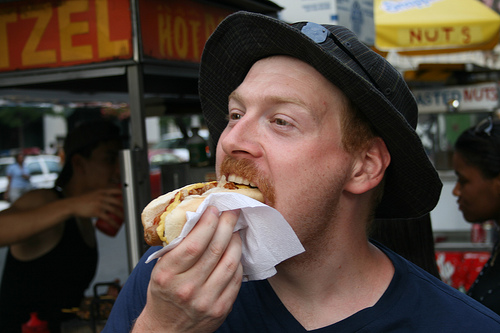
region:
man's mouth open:
[209, 153, 299, 213]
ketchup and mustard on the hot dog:
[146, 184, 283, 226]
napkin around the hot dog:
[168, 193, 328, 284]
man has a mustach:
[216, 158, 288, 195]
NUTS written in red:
[405, 10, 490, 49]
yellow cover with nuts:
[367, 0, 499, 61]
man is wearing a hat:
[187, 19, 477, 239]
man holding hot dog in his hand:
[151, 178, 314, 307]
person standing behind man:
[433, 111, 499, 244]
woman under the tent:
[11, 102, 140, 331]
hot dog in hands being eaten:
[135, 165, 267, 240]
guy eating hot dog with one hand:
[102, 13, 479, 331]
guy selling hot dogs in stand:
[7, 9, 169, 309]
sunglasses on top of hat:
[265, 8, 400, 92]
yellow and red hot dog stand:
[16, 6, 203, 104]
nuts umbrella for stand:
[375, 1, 499, 58]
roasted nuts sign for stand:
[406, 71, 498, 125]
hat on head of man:
[189, 5, 456, 203]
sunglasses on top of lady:
[456, 116, 498, 143]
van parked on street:
[0, 142, 82, 209]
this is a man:
[185, 55, 461, 315]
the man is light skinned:
[318, 152, 355, 217]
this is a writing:
[33, 14, 125, 56]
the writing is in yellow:
[30, 17, 108, 72]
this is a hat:
[315, 22, 367, 78]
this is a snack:
[150, 199, 190, 226]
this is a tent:
[398, 9, 490, 51]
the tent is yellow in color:
[426, 7, 471, 29]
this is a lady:
[446, 123, 499, 246]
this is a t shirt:
[410, 284, 485, 331]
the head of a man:
[189, 23, 430, 240]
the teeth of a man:
[207, 163, 253, 190]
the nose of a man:
[210, 120, 284, 167]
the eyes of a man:
[214, 107, 369, 139]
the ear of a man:
[328, 126, 416, 203]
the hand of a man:
[157, 201, 274, 324]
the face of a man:
[179, 55, 349, 228]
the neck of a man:
[256, 165, 428, 300]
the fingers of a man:
[149, 205, 256, 300]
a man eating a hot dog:
[122, 91, 372, 268]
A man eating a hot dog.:
[101, 8, 498, 331]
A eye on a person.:
[265, 108, 304, 136]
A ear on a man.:
[344, 129, 392, 198]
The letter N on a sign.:
[403, 24, 423, 45]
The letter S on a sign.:
[456, 20, 471, 43]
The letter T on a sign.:
[438, 22, 454, 44]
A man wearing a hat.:
[101, 8, 499, 330]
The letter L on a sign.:
[91, 0, 133, 60]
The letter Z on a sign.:
[14, 2, 59, 69]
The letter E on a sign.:
[52, 0, 99, 62]